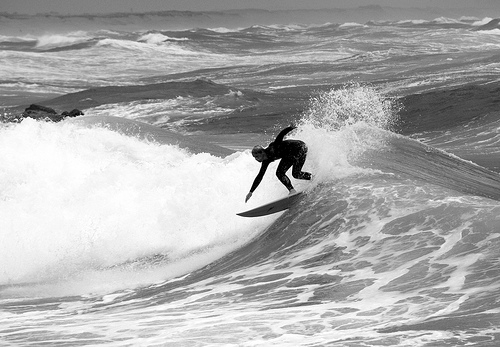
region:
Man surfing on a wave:
[235, 123, 331, 225]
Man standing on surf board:
[236, 119, 331, 226]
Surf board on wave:
[226, 191, 330, 228]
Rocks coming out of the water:
[9, 97, 94, 146]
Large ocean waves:
[10, 113, 457, 331]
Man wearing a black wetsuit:
[239, 122, 340, 202]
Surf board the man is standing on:
[230, 186, 317, 224]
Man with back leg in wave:
[232, 122, 344, 198]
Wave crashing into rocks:
[1, 112, 174, 262]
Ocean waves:
[0, 11, 496, 276]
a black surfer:
[226, 110, 324, 233]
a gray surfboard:
[215, 178, 320, 223]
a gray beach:
[2, 21, 498, 334]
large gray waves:
[2, 85, 499, 342]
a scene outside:
[6, 7, 494, 339]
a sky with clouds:
[10, 0, 499, 39]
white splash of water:
[0, 84, 417, 292]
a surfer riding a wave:
[210, 95, 377, 252]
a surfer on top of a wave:
[220, 106, 335, 248]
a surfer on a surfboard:
[209, 107, 336, 242]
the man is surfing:
[165, 79, 377, 239]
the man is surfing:
[202, 65, 422, 345]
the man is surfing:
[227, 83, 354, 325]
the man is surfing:
[171, 36, 323, 331]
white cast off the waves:
[283, 67, 410, 173]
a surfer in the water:
[213, 120, 345, 228]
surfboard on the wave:
[224, 190, 354, 226]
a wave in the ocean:
[124, 37, 257, 132]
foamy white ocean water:
[153, 224, 400, 327]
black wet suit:
[235, 110, 327, 192]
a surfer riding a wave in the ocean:
[204, 112, 348, 229]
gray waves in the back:
[20, 12, 465, 81]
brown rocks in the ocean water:
[9, 90, 104, 152]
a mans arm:
[240, 160, 270, 205]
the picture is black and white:
[0, 1, 496, 343]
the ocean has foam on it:
[6, 59, 490, 345]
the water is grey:
[1, 0, 499, 345]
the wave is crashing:
[0, 71, 417, 316]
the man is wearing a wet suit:
[238, 130, 320, 200]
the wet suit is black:
[239, 121, 321, 200]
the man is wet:
[238, 118, 327, 208]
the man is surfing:
[236, 121, 319, 203]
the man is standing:
[242, 122, 319, 202]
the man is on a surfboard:
[226, 121, 318, 223]